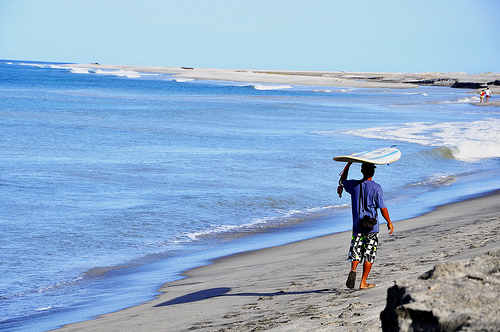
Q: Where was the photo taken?
A: It was taken at the shore.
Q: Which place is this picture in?
A: It is at the shore.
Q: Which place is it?
A: It is a shore.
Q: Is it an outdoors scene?
A: Yes, it is outdoors.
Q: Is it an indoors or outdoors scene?
A: It is outdoors.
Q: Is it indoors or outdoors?
A: It is outdoors.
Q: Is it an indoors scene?
A: No, it is outdoors.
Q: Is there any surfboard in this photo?
A: Yes, there is a surfboard.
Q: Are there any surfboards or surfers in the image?
A: Yes, there is a surfboard.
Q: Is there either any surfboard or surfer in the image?
A: Yes, there is a surfboard.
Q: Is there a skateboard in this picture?
A: No, there are no skateboards.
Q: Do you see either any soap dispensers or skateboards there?
A: No, there are no skateboards or soap dispensers.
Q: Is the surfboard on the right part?
A: Yes, the surfboard is on the right of the image.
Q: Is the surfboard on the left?
A: No, the surfboard is on the right of the image.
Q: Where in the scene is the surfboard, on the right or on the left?
A: The surfboard is on the right of the image.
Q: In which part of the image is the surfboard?
A: The surfboard is on the right of the image.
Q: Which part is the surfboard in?
A: The surfboard is on the right of the image.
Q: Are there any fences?
A: No, there are no fences.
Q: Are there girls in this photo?
A: No, there are no girls.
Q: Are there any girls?
A: No, there are no girls.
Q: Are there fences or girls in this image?
A: No, there are no girls or fences.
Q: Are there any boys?
A: No, there are no boys.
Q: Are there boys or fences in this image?
A: No, there are no boys or fences.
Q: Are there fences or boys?
A: No, there are no boys or fences.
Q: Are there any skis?
A: No, there are no skis.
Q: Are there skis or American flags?
A: No, there are no skis or American flags.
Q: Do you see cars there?
A: No, there are no cars.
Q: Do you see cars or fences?
A: No, there are no cars or fences.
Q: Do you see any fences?
A: No, there are no fences.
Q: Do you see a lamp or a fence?
A: No, there are no fences or lamps.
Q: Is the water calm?
A: Yes, the water is calm.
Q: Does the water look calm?
A: Yes, the water is calm.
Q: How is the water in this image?
A: The water is calm.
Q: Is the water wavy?
A: No, the water is calm.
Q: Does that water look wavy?
A: No, the water is calm.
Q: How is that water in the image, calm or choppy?
A: The water is calm.